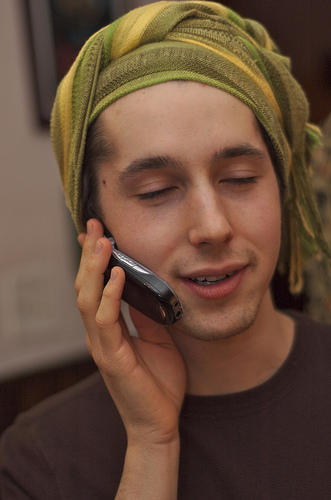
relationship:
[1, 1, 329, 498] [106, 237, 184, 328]
man on phone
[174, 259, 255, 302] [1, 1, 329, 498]
mouth on man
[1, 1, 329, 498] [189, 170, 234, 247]
man has nose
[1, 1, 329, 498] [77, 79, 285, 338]
man has face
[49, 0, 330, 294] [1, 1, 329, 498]
cover on top of man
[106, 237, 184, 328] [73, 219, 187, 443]
phone in hand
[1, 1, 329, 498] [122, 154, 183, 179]
man has eyebrow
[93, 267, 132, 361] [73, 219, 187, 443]
finger on hand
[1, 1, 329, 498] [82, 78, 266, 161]
man has forehead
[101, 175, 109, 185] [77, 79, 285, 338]
mole on face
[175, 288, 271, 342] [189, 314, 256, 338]
stubble on chin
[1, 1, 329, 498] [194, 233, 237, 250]
man has nostrils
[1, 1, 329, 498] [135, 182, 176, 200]
man has eyelashes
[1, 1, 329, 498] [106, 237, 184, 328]
man holding phone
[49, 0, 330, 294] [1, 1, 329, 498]
cover on man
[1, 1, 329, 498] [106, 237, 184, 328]
man taking phone